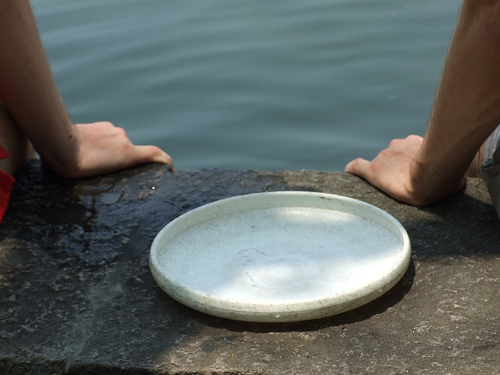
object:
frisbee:
[139, 184, 425, 327]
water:
[38, 0, 452, 172]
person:
[342, 0, 498, 214]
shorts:
[0, 137, 19, 224]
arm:
[410, 0, 499, 183]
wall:
[0, 170, 500, 374]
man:
[0, 0, 177, 225]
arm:
[0, 2, 79, 176]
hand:
[342, 135, 429, 206]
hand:
[66, 116, 175, 179]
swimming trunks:
[480, 125, 500, 185]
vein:
[448, 123, 479, 155]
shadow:
[411, 205, 499, 256]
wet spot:
[4, 159, 237, 265]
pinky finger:
[134, 143, 181, 171]